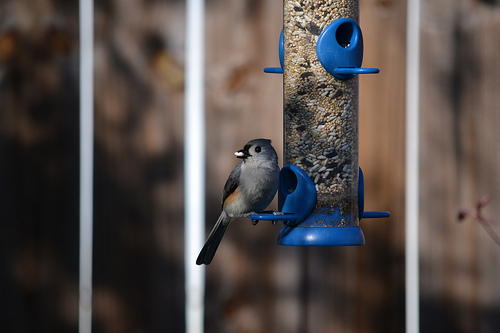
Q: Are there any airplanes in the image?
A: No, there are no airplanes.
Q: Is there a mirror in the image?
A: No, there are no mirrors.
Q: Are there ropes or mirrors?
A: No, there are no mirrors or ropes.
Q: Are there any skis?
A: No, there are no skis.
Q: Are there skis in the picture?
A: No, there are no skis.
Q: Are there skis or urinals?
A: No, there are no skis or urinals.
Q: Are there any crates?
A: No, there are no crates.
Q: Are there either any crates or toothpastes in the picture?
A: No, there are no crates or toothpastes.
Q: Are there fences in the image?
A: Yes, there is a fence.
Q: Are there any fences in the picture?
A: Yes, there is a fence.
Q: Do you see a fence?
A: Yes, there is a fence.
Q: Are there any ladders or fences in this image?
A: Yes, there is a fence.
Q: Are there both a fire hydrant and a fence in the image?
A: No, there is a fence but no fire hydrants.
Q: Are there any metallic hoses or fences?
A: Yes, there is a metal fence.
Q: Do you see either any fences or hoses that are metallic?
A: Yes, the fence is metallic.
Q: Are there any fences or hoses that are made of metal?
A: Yes, the fence is made of metal.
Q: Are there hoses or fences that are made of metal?
A: Yes, the fence is made of metal.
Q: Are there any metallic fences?
A: Yes, there is a metal fence.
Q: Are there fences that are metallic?
A: Yes, there is a fence that is metallic.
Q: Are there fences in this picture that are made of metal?
A: Yes, there is a fence that is made of metal.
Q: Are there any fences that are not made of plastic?
A: Yes, there is a fence that is made of metal.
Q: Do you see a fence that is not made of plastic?
A: Yes, there is a fence that is made of metal.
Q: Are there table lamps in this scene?
A: No, there are no table lamps.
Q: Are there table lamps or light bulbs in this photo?
A: No, there are no table lamps or light bulbs.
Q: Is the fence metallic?
A: Yes, the fence is metallic.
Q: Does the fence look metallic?
A: Yes, the fence is metallic.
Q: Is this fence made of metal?
A: Yes, the fence is made of metal.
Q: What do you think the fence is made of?
A: The fence is made of metal.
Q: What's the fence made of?
A: The fence is made of metal.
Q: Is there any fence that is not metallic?
A: No, there is a fence but it is metallic.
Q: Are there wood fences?
A: No, there is a fence but it is made of metal.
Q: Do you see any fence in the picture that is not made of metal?
A: No, there is a fence but it is made of metal.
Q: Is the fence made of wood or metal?
A: The fence is made of metal.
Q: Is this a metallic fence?
A: Yes, this is a metallic fence.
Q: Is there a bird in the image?
A: Yes, there is a bird.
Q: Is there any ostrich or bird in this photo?
A: Yes, there is a bird.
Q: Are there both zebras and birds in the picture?
A: No, there is a bird but no zebras.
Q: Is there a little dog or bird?
A: Yes, there is a little bird.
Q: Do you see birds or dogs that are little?
A: Yes, the bird is little.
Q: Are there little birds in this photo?
A: Yes, there is a little bird.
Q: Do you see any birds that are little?
A: Yes, there is a bird that is little.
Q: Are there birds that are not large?
A: Yes, there is a little bird.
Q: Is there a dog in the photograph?
A: No, there are no dogs.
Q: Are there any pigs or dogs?
A: No, there are no dogs or pigs.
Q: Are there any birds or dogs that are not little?
A: No, there is a bird but it is little.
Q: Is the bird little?
A: Yes, the bird is little.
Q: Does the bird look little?
A: Yes, the bird is little.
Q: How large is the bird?
A: The bird is little.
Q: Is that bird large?
A: No, the bird is little.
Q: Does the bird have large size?
A: No, the bird is little.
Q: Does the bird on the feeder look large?
A: No, the bird is little.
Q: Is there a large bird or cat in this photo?
A: No, there is a bird but it is little.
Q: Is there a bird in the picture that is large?
A: No, there is a bird but it is little.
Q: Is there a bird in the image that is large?
A: No, there is a bird but it is little.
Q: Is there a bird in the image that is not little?
A: No, there is a bird but it is little.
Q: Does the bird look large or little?
A: The bird is little.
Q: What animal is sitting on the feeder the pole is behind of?
A: The bird is sitting on the feeder.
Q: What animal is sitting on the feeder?
A: The bird is sitting on the feeder.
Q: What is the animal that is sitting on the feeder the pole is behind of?
A: The animal is a bird.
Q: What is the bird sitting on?
A: The bird is sitting on the feeder.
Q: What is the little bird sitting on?
A: The bird is sitting on the feeder.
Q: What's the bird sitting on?
A: The bird is sitting on the feeder.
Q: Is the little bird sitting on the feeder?
A: Yes, the bird is sitting on the feeder.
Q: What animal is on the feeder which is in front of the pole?
A: The bird is on the feeder.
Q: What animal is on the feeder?
A: The bird is on the feeder.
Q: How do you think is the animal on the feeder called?
A: The animal is a bird.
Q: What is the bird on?
A: The bird is on the feeder.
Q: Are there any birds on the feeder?
A: Yes, there is a bird on the feeder.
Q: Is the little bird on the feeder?
A: Yes, the bird is on the feeder.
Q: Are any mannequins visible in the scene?
A: No, there are no mannequins.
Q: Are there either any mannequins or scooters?
A: No, there are no mannequins or scooters.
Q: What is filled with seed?
A: The feeder is filled with seed.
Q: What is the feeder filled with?
A: The feeder is filled with seed.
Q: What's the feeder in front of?
A: The feeder is in front of the pole.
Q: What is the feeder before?
A: The feeder is in front of the pole.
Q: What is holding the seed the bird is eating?
A: The feeder is holding the seed.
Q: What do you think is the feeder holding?
A: The feeder is holding the seed.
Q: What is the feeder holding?
A: The feeder is holding the seed.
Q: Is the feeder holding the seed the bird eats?
A: Yes, the feeder is holding the seed.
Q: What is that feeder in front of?
A: The feeder is in front of the pole.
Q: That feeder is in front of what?
A: The feeder is in front of the pole.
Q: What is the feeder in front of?
A: The feeder is in front of the pole.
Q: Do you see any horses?
A: No, there are no horses.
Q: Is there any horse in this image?
A: No, there are no horses.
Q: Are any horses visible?
A: No, there are no horses.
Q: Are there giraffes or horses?
A: No, there are no horses or giraffes.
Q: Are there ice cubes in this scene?
A: No, there are no ice cubes.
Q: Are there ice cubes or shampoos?
A: No, there are no ice cubes or shampoos.